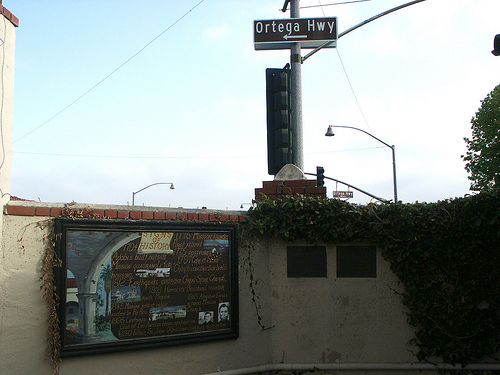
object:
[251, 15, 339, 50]
directional sign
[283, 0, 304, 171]
utility pole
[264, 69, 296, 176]
traffic light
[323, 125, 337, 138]
streetlight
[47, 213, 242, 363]
picture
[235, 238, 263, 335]
ivy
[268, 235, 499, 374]
wall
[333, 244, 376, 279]
plaques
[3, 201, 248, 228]
edge of building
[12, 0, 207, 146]
electrical wire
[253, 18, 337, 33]
ortega hwy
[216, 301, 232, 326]
abraham lincoln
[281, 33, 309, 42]
arrow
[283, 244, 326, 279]
square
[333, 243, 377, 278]
square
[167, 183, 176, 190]
streetlight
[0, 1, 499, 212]
sky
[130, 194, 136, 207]
pole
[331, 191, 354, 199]
road sign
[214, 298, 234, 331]
picture